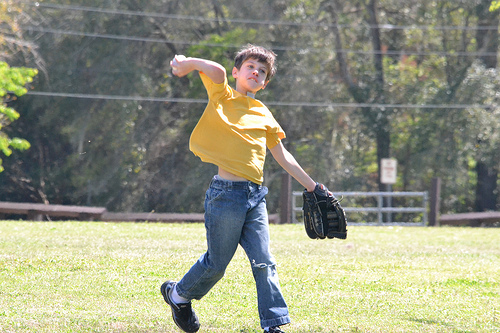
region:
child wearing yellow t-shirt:
[158, 30, 312, 200]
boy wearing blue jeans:
[161, 60, 313, 330]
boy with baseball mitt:
[227, 59, 350, 246]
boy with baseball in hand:
[146, 21, 349, 322]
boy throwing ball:
[149, 27, 344, 211]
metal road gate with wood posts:
[280, 165, 436, 235]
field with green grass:
[15, 227, 495, 327]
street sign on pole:
[370, 147, 405, 222]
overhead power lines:
[8, 0, 490, 125]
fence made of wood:
[6, 170, 499, 226]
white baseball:
[161, 50, 183, 70]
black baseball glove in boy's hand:
[295, 184, 364, 235]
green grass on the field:
[24, 248, 117, 297]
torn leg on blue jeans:
[242, 257, 301, 286]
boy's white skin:
[211, 168, 240, 180]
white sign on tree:
[375, 145, 408, 189]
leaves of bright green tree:
[3, 86, 23, 145]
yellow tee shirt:
[168, 76, 311, 192]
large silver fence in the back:
[317, 175, 416, 237]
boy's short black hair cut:
[236, 38, 286, 73]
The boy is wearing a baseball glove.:
[141, 18, 352, 332]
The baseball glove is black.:
[157, 34, 354, 331]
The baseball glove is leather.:
[144, 22, 361, 332]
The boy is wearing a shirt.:
[136, 29, 356, 331]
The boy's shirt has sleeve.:
[152, 28, 349, 332]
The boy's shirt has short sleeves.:
[145, 15, 355, 330]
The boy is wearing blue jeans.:
[146, 31, 353, 331]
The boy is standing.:
[136, 18, 371, 331]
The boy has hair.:
[148, 30, 353, 244]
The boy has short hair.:
[168, 25, 374, 261]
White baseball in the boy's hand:
[170, 53, 185, 76]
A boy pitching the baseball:
[160, 43, 345, 331]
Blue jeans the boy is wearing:
[175, 175, 290, 327]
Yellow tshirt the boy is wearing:
[187, 72, 284, 182]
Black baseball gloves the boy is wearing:
[301, 183, 347, 240]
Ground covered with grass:
[0, 224, 497, 331]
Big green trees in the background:
[1, 0, 498, 216]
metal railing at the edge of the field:
[282, 175, 442, 225]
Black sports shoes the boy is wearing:
[160, 281, 282, 331]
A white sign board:
[379, 158, 396, 183]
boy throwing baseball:
[37, 23, 423, 332]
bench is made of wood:
[3, 196, 110, 223]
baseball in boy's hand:
[167, 55, 198, 80]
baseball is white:
[156, 46, 192, 86]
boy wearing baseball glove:
[286, 185, 363, 256]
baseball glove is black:
[302, 170, 355, 270]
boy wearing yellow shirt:
[191, 70, 297, 203]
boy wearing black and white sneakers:
[135, 261, 212, 331]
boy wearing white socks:
[165, 277, 200, 303]